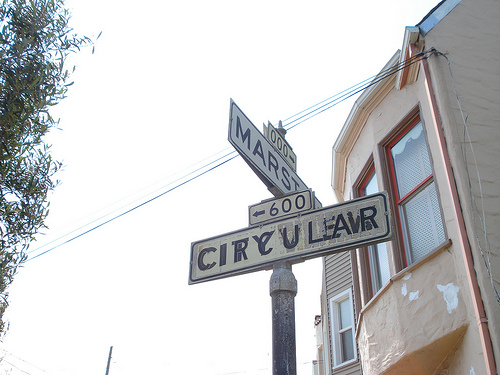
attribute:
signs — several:
[216, 126, 397, 248]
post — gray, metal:
[235, 269, 375, 371]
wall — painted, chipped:
[352, 246, 486, 373]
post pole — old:
[266, 261, 298, 373]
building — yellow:
[309, 0, 498, 374]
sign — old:
[224, 96, 326, 211]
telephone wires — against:
[12, 47, 449, 272]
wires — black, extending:
[41, 32, 442, 274]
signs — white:
[166, 94, 429, 274]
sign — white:
[141, 190, 452, 314]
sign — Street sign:
[228, 102, 324, 217]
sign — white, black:
[176, 89, 409, 289]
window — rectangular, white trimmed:
[323, 274, 365, 371]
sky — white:
[108, 32, 197, 94]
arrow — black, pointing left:
[241, 202, 266, 221]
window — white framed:
[323, 285, 378, 367]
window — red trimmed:
[381, 101, 453, 278]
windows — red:
[360, 110, 481, 262]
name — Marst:
[234, 114, 302, 194]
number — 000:
[268, 127, 290, 158]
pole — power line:
[104, 344, 114, 374]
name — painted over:
[197, 203, 379, 270]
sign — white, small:
[247, 187, 314, 227]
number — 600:
[268, 194, 308, 216]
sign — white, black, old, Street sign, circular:
[187, 190, 395, 284]